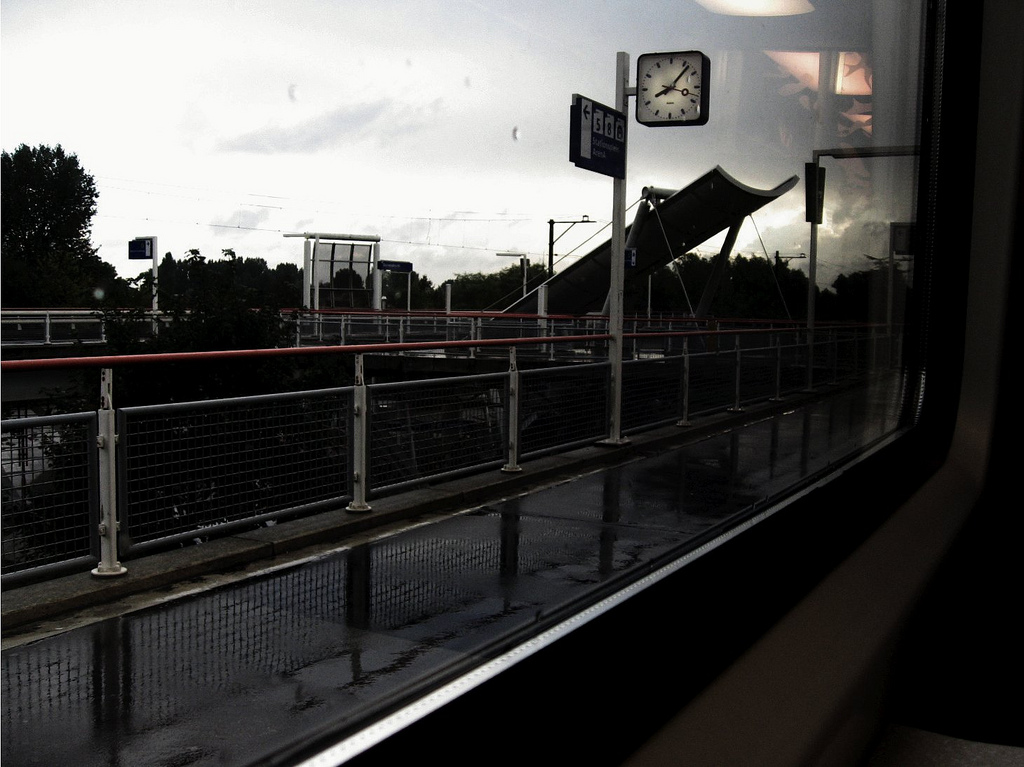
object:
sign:
[570, 93, 627, 179]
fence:
[9, 411, 116, 571]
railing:
[2, 325, 827, 371]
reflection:
[2, 471, 683, 762]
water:
[69, 512, 679, 727]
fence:
[366, 383, 514, 480]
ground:
[6, 394, 1018, 753]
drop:
[511, 124, 522, 139]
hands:
[654, 68, 700, 98]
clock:
[636, 50, 708, 127]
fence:
[124, 383, 349, 529]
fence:
[374, 517, 512, 619]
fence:
[514, 478, 607, 581]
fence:
[517, 359, 609, 454]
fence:
[739, 424, 775, 490]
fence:
[622, 355, 682, 434]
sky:
[4, 0, 897, 269]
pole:
[91, 366, 124, 579]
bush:
[5, 150, 97, 308]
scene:
[0, 6, 897, 619]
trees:
[161, 256, 282, 312]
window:
[8, 1, 945, 764]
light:
[769, 50, 873, 97]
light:
[841, 107, 876, 139]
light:
[701, 0, 813, 18]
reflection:
[695, 4, 876, 144]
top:
[5, 329, 615, 366]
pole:
[607, 40, 634, 559]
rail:
[121, 383, 361, 415]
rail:
[130, 496, 343, 546]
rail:
[371, 458, 504, 493]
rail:
[525, 357, 611, 381]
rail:
[690, 403, 737, 415]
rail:
[621, 350, 686, 369]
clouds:
[208, 96, 436, 154]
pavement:
[17, 445, 873, 663]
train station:
[5, 244, 917, 763]